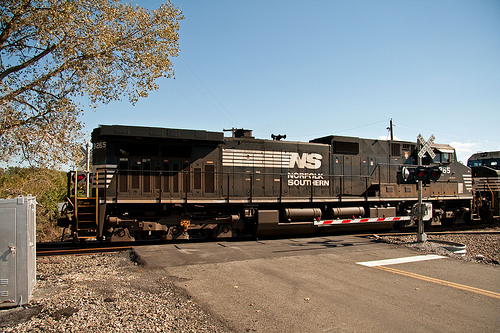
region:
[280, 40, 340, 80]
A clear blue sky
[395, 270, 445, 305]
Two solid yellow lines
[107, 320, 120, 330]
A few rocks in the ground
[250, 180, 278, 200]
Side of the moving train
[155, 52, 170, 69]
Yellow leaves on the tree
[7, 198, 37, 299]
A huge gray electricity box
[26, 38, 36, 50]
One of the many branches on the tree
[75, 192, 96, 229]
Yellow ladder on the train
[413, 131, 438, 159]
Sign that reads railroad crossing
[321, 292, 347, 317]
Small part of the black street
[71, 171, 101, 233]
train has a yellow ladder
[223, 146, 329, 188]
Letters NS on the side of train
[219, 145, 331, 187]
NS stands for Norfolk Southern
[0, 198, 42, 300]
electrical box is on gravel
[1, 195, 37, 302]
electrical box is gray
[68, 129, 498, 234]
train is on the track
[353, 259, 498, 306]
street has double solid lines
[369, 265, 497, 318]
double solid lines on street are yellow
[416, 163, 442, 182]
railroad crossing lights are red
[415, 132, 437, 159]
railroad crossing sign is an X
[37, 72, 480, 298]
train crossing over paved road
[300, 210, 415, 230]
red and white striped warning strip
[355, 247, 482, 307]
thick white line at end of double yellow lines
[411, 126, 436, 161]
black words on crossed white signs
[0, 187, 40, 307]
metal control box on side of road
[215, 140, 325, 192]
white stripes leading to name of railroad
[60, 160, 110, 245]
yellow ladder in front of red light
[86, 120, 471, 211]
flat side of train composed on compartments and panels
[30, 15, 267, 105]
tree against clear blue sky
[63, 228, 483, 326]
gravel on sides of road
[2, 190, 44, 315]
Utility box in the gravel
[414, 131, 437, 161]
Railroad crossing sign on pole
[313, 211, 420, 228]
Gate for road crossing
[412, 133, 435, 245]
Support pole for railroad crossing signs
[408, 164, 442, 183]
Warning lights on railroad crossing sign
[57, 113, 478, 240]
Locomotive on the railroad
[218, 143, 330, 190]
Logo on railroad locomotive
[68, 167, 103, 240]
Access ladder on railroad locomotive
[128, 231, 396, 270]
Asphalt ramp for railroad crossing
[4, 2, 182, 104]
Branches of a tree next to the railroad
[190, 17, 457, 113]
The sky is clear.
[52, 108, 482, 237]
The train is black.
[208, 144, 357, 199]
The train has white letters.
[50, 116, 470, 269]
The train is not moving.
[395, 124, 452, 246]
The rail road crossing sign is white.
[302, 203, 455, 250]
The gate is down.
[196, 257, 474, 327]
The street is grey.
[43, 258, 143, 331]
The ground is rocky.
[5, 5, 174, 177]
The tree has leaves on it.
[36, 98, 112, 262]
The stairs are yellow.